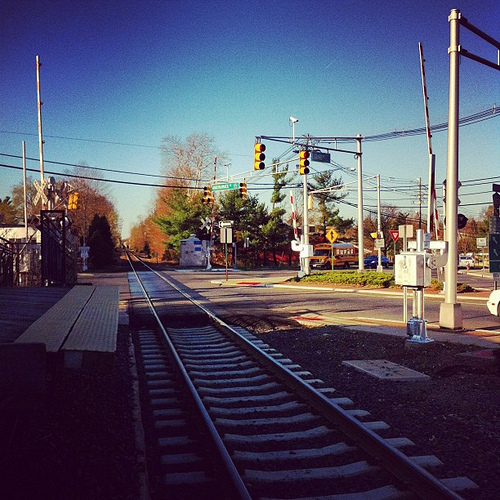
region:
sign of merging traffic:
[320, 222, 346, 244]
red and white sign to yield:
[388, 224, 400, 246]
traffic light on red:
[248, 133, 313, 180]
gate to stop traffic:
[409, 33, 445, 255]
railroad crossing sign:
[26, 176, 55, 226]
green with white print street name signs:
[204, 150, 339, 196]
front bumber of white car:
[482, 286, 499, 316]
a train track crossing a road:
[123, 240, 469, 498]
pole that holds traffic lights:
[438, 7, 494, 329]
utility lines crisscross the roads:
[3, 115, 499, 215]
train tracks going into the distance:
[112, 235, 489, 497]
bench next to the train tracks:
[7, 276, 127, 360]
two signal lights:
[248, 138, 319, 179]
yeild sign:
[386, 225, 403, 258]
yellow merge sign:
[322, 225, 340, 277]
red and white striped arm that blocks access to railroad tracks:
[283, 185, 308, 262]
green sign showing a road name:
[208, 180, 244, 195]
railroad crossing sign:
[28, 173, 50, 208]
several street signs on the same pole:
[483, 178, 498, 294]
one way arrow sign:
[217, 216, 236, 229]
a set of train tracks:
[121, 243, 451, 498]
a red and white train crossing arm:
[286, 188, 311, 259]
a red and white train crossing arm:
[31, 48, 55, 215]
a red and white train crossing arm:
[412, 37, 442, 261]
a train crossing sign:
[194, 210, 211, 232]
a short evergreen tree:
[84, 210, 116, 267]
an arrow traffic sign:
[215, 217, 232, 228]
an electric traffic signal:
[252, 138, 266, 171]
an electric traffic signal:
[297, 143, 310, 175]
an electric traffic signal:
[237, 178, 248, 200]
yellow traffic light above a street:
[250, 137, 270, 174]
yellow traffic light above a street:
[292, 147, 312, 177]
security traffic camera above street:
[285, 115, 300, 142]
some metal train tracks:
[110, 230, 489, 498]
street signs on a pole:
[213, 215, 236, 282]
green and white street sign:
[208, 177, 242, 196]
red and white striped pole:
[415, 39, 449, 272]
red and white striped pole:
[32, 50, 45, 212]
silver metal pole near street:
[435, 3, 476, 339]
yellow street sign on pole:
[324, 228, 342, 278]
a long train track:
[121, 235, 461, 499]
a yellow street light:
[255, 143, 269, 171]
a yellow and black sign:
[326, 225, 338, 240]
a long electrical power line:
[3, 147, 210, 189]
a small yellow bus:
[304, 239, 354, 277]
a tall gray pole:
[435, 10, 476, 333]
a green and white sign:
[208, 181, 243, 190]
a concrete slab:
[342, 348, 428, 387]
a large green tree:
[253, 152, 292, 252]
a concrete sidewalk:
[212, 256, 288, 286]